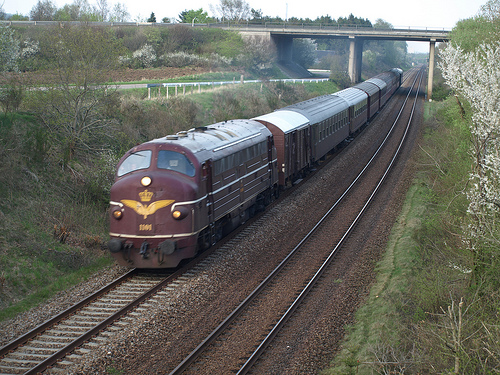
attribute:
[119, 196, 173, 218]
bird — yellow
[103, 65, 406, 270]
train — maroon, traveling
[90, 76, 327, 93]
gate — white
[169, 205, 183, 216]
light — yellow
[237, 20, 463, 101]
bridge — concrete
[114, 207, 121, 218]
headlight — yellow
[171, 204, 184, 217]
headlight — yellow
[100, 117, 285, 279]
engine car — golden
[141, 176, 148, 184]
headlight — white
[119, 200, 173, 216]
wings — golden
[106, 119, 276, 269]
engine — red, burgundy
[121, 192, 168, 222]
eagle — painted, golden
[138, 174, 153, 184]
light — round, circular, white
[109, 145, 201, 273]
front — maroon, gold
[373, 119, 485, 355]
shrubbery — green, brown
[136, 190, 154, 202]
crown — painted, golden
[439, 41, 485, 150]
blossoms — white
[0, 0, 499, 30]
sky — white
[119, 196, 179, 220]
design — bird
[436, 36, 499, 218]
blossoms — white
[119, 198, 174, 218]
design — gold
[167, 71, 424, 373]
train track — cross tied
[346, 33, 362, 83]
support — concrete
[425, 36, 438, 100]
support — concrete